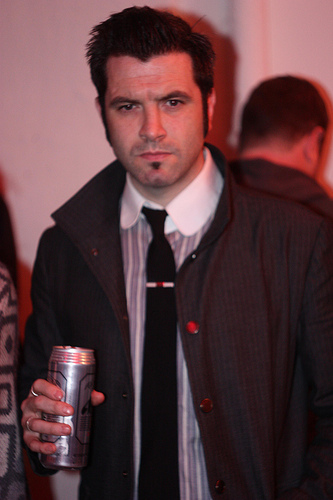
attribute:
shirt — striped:
[119, 182, 223, 498]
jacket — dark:
[14, 142, 332, 499]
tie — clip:
[139, 206, 180, 499]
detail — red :
[155, 280, 163, 289]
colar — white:
[171, 168, 229, 229]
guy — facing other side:
[59, 12, 263, 186]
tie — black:
[140, 206, 178, 415]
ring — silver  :
[29, 381, 41, 399]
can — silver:
[35, 338, 102, 464]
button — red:
[201, 393, 217, 416]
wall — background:
[0, 1, 97, 151]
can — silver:
[37, 342, 95, 472]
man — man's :
[19, 4, 330, 498]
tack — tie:
[143, 280, 173, 289]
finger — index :
[18, 374, 103, 461]